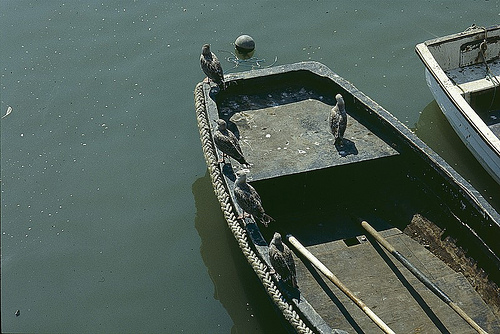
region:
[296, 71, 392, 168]
a pigeon on a boat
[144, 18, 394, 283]
pigeons on a boat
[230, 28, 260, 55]
ballast in the water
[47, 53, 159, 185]
the water is calm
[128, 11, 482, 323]
the boat has pigeons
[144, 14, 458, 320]
a flock of pigeons on a rowboat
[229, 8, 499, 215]
two boats docked together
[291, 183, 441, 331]
the oars are in the boat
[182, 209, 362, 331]
the boat has rope trim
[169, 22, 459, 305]
the rowboat is wooden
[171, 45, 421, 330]
brown boat in water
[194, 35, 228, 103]
bird on brown colored boat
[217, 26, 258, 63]
bird on brown colored boat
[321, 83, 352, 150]
bird on brown colored boat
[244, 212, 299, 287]
bird on brown colored boat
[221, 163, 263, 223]
bird on brown colored boat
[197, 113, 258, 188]
bird on brown colored boat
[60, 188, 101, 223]
ripples in green colored ocean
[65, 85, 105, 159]
ripples in green colored ocean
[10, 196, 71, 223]
ripples in green colored ocean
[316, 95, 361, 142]
bird on the boat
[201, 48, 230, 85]
bird on the boat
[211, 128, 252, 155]
bird on the boat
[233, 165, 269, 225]
bird on the boat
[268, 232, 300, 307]
bird on the boat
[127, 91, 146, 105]
speck in the water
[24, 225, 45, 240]
speck in the water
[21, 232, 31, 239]
speck in the water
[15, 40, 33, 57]
speck in the water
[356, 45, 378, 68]
speck in the water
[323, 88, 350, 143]
a large bird in a boat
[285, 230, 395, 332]
a white boat oar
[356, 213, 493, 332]
a gray and black boat oar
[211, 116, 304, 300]
a row of birds on the edge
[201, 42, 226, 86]
a bird on the front edge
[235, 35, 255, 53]
a round metal ball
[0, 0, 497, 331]
two boats in murky black water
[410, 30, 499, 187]
front edge of a white boat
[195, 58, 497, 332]
a black boat in the water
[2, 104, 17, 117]
white debris in the water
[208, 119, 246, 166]
bird on the boat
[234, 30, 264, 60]
ball in the water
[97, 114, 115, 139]
spot in the water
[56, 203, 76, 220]
spot in the water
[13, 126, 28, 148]
spot in the water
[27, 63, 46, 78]
spot in the water